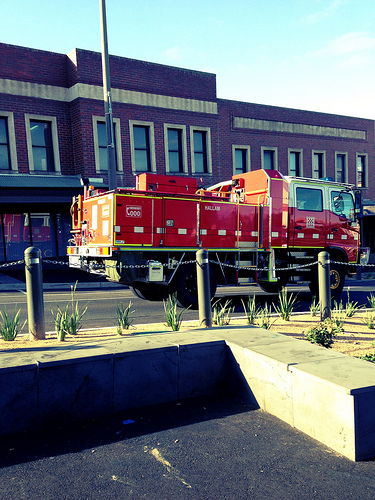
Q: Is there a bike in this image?
A: No, there are no bikes.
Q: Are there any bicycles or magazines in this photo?
A: No, there are no bicycles or magazines.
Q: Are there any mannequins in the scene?
A: No, there are no mannequins.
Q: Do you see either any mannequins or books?
A: No, there are no mannequins or books.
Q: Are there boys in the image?
A: No, there are no boys.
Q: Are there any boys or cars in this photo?
A: No, there are no boys or cars.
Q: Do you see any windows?
A: Yes, there is a window.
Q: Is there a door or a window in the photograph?
A: Yes, there is a window.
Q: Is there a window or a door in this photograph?
A: Yes, there is a window.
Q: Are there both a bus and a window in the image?
A: No, there is a window but no buses.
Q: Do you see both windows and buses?
A: No, there is a window but no buses.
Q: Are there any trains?
A: No, there are no trains.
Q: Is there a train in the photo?
A: No, there are no trains.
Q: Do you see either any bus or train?
A: No, there are no trains or buses.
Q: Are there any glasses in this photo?
A: No, there are no glasses.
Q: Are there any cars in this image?
A: No, there are no cars.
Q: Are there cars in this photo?
A: No, there are no cars.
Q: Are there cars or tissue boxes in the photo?
A: No, there are no cars or tissue boxes.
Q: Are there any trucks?
A: Yes, there is a truck.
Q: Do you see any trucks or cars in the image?
A: Yes, there is a truck.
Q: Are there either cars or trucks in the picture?
A: Yes, there is a truck.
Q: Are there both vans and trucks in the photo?
A: No, there is a truck but no vans.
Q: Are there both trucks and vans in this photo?
A: No, there is a truck but no vans.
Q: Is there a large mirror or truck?
A: Yes, there is a large truck.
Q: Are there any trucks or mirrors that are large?
A: Yes, the truck is large.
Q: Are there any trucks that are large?
A: Yes, there is a truck that is large.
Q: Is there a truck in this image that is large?
A: Yes, there is a truck that is large.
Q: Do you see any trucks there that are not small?
A: Yes, there is a large truck.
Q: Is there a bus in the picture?
A: No, there are no buses.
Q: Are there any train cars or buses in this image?
A: No, there are no buses or train cars.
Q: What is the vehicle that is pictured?
A: The vehicle is a truck.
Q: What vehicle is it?
A: The vehicle is a truck.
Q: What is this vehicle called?
A: This is a truck.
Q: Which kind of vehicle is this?
A: This is a truck.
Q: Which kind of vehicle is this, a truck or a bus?
A: This is a truck.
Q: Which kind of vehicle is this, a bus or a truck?
A: This is a truck.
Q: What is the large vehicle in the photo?
A: The vehicle is a truck.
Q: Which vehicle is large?
A: The vehicle is a truck.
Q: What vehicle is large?
A: The vehicle is a truck.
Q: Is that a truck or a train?
A: That is a truck.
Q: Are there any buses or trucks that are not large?
A: No, there is a truck but it is large.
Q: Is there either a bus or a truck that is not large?
A: No, there is a truck but it is large.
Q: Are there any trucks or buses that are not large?
A: No, there is a truck but it is large.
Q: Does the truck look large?
A: Yes, the truck is large.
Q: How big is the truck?
A: The truck is large.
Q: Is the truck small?
A: No, the truck is large.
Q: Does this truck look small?
A: No, the truck is large.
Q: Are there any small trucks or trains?
A: No, there is a truck but it is large.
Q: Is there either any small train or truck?
A: No, there is a truck but it is large.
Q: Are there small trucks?
A: No, there is a truck but it is large.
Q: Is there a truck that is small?
A: No, there is a truck but it is large.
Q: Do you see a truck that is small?
A: No, there is a truck but it is large.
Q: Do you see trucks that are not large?
A: No, there is a truck but it is large.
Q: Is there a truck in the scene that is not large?
A: No, there is a truck but it is large.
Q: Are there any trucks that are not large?
A: No, there is a truck but it is large.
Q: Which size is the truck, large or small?
A: The truck is large.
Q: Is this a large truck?
A: Yes, this is a large truck.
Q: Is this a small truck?
A: No, this is a large truck.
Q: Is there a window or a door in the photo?
A: Yes, there is a window.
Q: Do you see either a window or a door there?
A: Yes, there is a window.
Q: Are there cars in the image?
A: No, there are no cars.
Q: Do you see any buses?
A: No, there are no buses.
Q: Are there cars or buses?
A: No, there are no buses or cars.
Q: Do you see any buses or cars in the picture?
A: No, there are no buses or cars.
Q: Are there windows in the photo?
A: Yes, there is a window.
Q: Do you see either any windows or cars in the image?
A: Yes, there is a window.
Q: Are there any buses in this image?
A: No, there are no buses.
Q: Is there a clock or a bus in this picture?
A: No, there are no buses or clocks.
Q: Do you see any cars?
A: No, there are no cars.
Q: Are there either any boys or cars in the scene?
A: No, there are no cars or boys.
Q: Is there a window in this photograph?
A: Yes, there is a window.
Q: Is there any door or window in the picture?
A: Yes, there is a window.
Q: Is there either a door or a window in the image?
A: Yes, there is a window.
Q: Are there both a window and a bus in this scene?
A: No, there is a window but no buses.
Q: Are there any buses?
A: No, there are no buses.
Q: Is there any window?
A: Yes, there is a window.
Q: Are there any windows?
A: Yes, there is a window.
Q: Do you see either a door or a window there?
A: Yes, there is a window.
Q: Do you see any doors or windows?
A: Yes, there is a window.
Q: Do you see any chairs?
A: No, there are no chairs.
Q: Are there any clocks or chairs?
A: No, there are no chairs or clocks.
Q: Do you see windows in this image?
A: Yes, there is a window.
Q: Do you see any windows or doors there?
A: Yes, there is a window.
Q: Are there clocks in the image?
A: No, there are no clocks.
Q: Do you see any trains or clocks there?
A: No, there are no clocks or trains.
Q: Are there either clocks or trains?
A: No, there are no clocks or trains.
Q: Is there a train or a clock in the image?
A: No, there are no clocks or trains.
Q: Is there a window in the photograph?
A: Yes, there is a window.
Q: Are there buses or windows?
A: Yes, there is a window.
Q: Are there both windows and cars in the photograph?
A: No, there is a window but no cars.